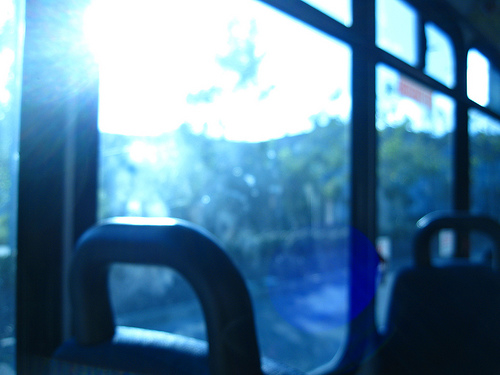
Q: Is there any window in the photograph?
A: Yes, there is a window.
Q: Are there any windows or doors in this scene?
A: Yes, there is a window.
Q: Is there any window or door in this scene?
A: Yes, there is a window.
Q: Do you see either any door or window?
A: Yes, there is a window.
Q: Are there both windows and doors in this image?
A: No, there is a window but no doors.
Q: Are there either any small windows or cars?
A: Yes, there is a small window.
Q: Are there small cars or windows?
A: Yes, there is a small window.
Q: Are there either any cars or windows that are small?
A: Yes, the window is small.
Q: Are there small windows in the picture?
A: Yes, there is a small window.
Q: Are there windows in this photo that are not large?
A: Yes, there is a small window.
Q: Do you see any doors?
A: No, there are no doors.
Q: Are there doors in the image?
A: No, there are no doors.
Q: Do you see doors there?
A: No, there are no doors.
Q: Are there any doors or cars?
A: No, there are no doors or cars.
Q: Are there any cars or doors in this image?
A: No, there are no doors or cars.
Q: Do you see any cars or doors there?
A: No, there are no doors or cars.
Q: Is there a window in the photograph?
A: Yes, there is a window.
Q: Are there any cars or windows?
A: Yes, there is a window.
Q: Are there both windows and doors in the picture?
A: No, there is a window but no doors.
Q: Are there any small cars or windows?
A: Yes, there is a small window.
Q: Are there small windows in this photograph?
A: Yes, there is a small window.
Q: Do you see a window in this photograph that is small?
A: Yes, there is a window that is small.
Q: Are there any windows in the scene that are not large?
A: Yes, there is a small window.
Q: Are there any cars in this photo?
A: No, there are no cars.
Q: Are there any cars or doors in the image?
A: No, there are no cars or doors.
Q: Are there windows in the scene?
A: Yes, there is a window.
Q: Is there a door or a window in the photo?
A: Yes, there is a window.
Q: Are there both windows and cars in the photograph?
A: No, there is a window but no cars.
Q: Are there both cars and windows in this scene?
A: No, there is a window but no cars.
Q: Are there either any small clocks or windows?
A: Yes, there is a small window.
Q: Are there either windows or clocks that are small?
A: Yes, the window is small.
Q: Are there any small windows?
A: Yes, there is a small window.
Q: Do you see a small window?
A: Yes, there is a small window.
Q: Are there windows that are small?
A: Yes, there is a window that is small.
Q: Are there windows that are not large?
A: Yes, there is a small window.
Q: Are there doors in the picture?
A: No, there are no doors.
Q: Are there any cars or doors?
A: No, there are no doors or cars.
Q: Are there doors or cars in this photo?
A: No, there are no doors or cars.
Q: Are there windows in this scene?
A: Yes, there is a window.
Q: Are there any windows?
A: Yes, there is a window.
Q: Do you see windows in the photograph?
A: Yes, there is a window.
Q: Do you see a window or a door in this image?
A: Yes, there is a window.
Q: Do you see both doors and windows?
A: No, there is a window but no doors.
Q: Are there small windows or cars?
A: Yes, there is a small window.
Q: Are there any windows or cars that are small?
A: Yes, the window is small.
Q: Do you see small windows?
A: Yes, there is a small window.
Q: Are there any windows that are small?
A: Yes, there is a window that is small.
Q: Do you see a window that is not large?
A: Yes, there is a small window.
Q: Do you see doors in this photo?
A: No, there are no doors.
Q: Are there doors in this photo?
A: No, there are no doors.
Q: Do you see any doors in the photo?
A: No, there are no doors.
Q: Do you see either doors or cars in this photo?
A: No, there are no doors or cars.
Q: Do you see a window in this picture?
A: Yes, there is a window.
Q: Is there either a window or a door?
A: Yes, there is a window.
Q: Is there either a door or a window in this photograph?
A: Yes, there is a window.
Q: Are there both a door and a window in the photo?
A: No, there is a window but no doors.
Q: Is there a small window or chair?
A: Yes, there is a small window.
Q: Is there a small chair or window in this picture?
A: Yes, there is a small window.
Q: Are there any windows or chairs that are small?
A: Yes, the window is small.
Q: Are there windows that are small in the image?
A: Yes, there is a small window.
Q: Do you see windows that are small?
A: Yes, there is a window that is small.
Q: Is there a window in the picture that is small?
A: Yes, there is a window that is small.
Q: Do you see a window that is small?
A: Yes, there is a window that is small.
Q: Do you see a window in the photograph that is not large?
A: Yes, there is a small window.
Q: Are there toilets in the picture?
A: No, there are no toilets.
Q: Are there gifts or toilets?
A: No, there are no toilets or gifts.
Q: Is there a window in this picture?
A: Yes, there is a window.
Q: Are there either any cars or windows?
A: Yes, there is a window.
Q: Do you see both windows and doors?
A: No, there is a window but no doors.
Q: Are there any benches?
A: No, there are no benches.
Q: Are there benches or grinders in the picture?
A: No, there are no benches or grinders.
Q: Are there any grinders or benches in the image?
A: No, there are no benches or grinders.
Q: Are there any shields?
A: No, there are no shields.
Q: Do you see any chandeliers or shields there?
A: No, there are no shields or chandeliers.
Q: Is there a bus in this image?
A: Yes, there is a bus.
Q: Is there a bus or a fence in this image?
A: Yes, there is a bus.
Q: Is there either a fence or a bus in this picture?
A: Yes, there is a bus.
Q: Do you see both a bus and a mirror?
A: No, there is a bus but no mirrors.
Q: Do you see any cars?
A: No, there are no cars.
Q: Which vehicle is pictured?
A: The vehicle is a bus.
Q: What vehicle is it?
A: The vehicle is a bus.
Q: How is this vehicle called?
A: This is a bus.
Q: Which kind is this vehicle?
A: This is a bus.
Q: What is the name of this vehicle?
A: This is a bus.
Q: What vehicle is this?
A: This is a bus.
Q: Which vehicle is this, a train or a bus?
A: This is a bus.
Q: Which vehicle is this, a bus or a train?
A: This is a bus.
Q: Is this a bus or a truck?
A: This is a bus.